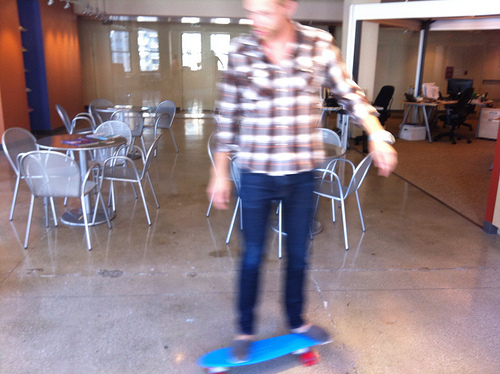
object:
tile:
[0, 287, 499, 372]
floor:
[0, 113, 499, 373]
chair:
[17, 149, 112, 252]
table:
[93, 104, 150, 162]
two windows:
[181, 31, 232, 71]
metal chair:
[312, 150, 376, 251]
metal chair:
[55, 103, 97, 135]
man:
[203, 0, 398, 362]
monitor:
[446, 78, 475, 97]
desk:
[395, 92, 493, 144]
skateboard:
[195, 331, 322, 373]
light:
[181, 32, 202, 71]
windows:
[137, 28, 161, 73]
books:
[60, 137, 100, 148]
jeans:
[231, 167, 318, 337]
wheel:
[296, 349, 321, 367]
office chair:
[433, 87, 476, 145]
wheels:
[451, 140, 458, 145]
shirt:
[210, 18, 381, 179]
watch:
[367, 129, 396, 146]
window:
[209, 33, 231, 72]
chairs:
[130, 100, 179, 159]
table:
[227, 140, 350, 236]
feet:
[287, 320, 330, 342]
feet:
[228, 329, 256, 361]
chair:
[90, 132, 164, 228]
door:
[178, 30, 237, 113]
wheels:
[202, 365, 229, 373]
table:
[34, 133, 128, 226]